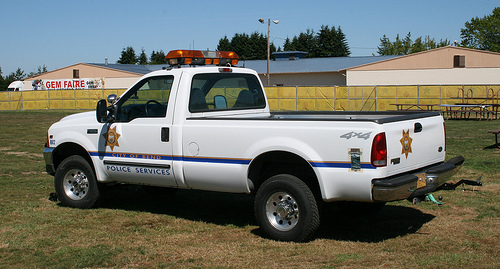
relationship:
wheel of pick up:
[252, 172, 322, 241] [42, 47, 464, 240]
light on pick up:
[370, 129, 398, 169] [42, 47, 464, 240]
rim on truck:
[258, 189, 301, 230] [36, 49, 447, 246]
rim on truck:
[61, 167, 88, 199] [36, 49, 447, 246]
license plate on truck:
[412, 167, 432, 192] [36, 49, 447, 246]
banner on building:
[44, 78, 87, 86] [10, 45, 498, 92]